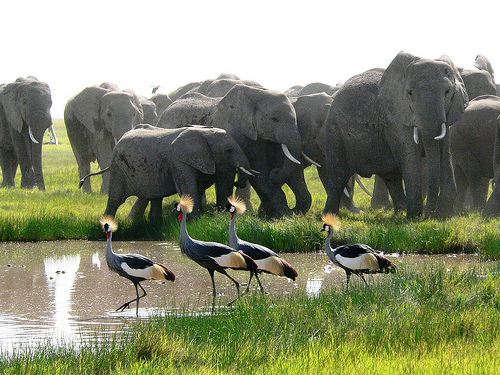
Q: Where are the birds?
A: In the water.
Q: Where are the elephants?
A: Near the water.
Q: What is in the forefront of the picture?
A: Grass.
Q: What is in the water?
A: Birds.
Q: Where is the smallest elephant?
A: By the water.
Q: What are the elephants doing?
A: Walking.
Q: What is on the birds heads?
A: Feathers.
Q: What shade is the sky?
A: Light.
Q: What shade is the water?
A: Brown.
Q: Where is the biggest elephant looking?
A: Forward.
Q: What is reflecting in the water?
A: Elephants.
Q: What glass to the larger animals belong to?
A: Mammal.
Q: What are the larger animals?
A: Elephants.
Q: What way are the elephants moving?
A: Left to right.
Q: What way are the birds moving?
A: Right to left.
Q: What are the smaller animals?
A: Birds.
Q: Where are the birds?
A: In the water.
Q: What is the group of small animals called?
A: Birds.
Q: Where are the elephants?
A: On the grass.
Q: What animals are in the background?
A: Elephants.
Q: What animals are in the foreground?
A: Peacocks.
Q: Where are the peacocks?
A: In the water.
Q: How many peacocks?
A: Four.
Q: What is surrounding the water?
A: Grass.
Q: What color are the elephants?
A: Grey.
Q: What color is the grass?
A: Green.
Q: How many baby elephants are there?
A: One.